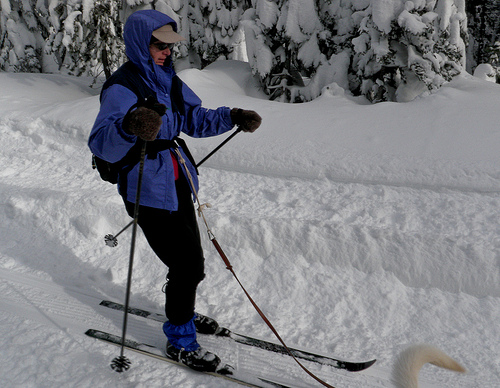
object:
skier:
[86, 9, 260, 368]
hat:
[153, 25, 182, 44]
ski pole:
[102, 128, 240, 245]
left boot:
[186, 313, 221, 336]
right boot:
[163, 338, 222, 371]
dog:
[394, 344, 469, 388]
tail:
[393, 343, 464, 386]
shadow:
[3, 187, 169, 354]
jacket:
[87, 12, 234, 211]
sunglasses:
[153, 40, 175, 50]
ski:
[95, 298, 375, 371]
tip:
[346, 357, 376, 373]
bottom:
[103, 232, 118, 249]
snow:
[2, 87, 496, 387]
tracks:
[6, 113, 85, 159]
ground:
[3, 68, 497, 387]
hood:
[124, 10, 179, 68]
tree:
[243, 0, 469, 103]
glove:
[229, 107, 261, 134]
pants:
[126, 177, 200, 347]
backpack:
[93, 59, 183, 184]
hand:
[232, 107, 261, 134]